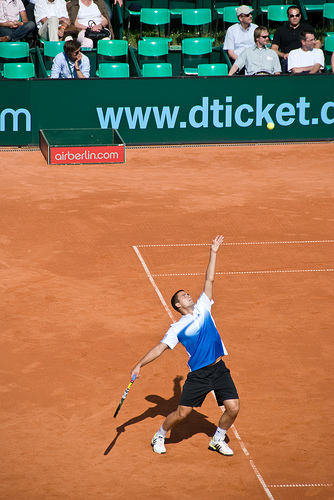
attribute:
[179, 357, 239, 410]
shorts — black in color, black, black colored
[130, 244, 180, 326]
line — white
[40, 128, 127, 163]
box — advertisement, green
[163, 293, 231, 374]
shirt — blue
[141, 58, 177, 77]
seat — green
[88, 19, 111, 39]
bag — black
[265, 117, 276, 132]
ball — yellow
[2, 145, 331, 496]
court — brown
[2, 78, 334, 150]
advertisement — displayed